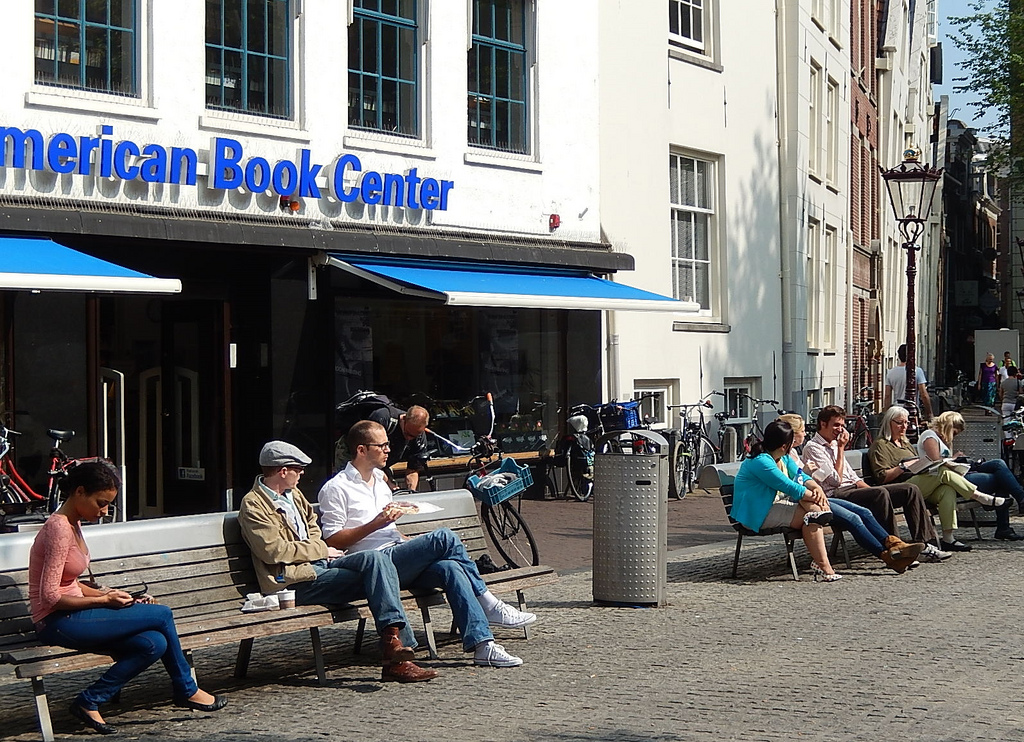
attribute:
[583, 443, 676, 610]
trashcan — tall, gray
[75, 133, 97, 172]
letters — blue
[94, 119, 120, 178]
letters — blue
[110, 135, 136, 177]
letters — blue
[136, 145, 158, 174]
letters — blue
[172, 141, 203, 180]
letters — blue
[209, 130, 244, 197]
letter — blue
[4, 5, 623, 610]
building — white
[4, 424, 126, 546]
bicycle — red